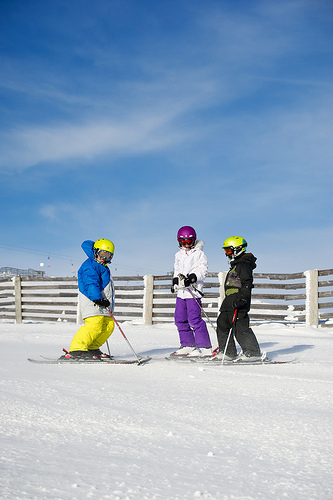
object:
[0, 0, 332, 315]
sky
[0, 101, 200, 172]
cloud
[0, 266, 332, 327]
fence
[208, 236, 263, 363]
skier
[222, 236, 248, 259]
helmet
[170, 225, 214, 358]
skier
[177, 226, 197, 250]
helmet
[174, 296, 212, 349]
ski pants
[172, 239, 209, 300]
jacket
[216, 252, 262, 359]
ski outfit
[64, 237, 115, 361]
skier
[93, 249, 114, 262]
snow goggles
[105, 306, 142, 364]
ski pole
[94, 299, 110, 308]
hand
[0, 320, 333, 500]
snow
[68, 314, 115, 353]
pants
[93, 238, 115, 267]
helmet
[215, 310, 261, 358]
pants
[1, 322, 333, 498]
ground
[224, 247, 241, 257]
snow goggles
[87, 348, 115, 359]
shoe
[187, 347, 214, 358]
shoe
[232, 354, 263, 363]
shoe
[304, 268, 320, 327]
fence post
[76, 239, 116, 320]
jacket